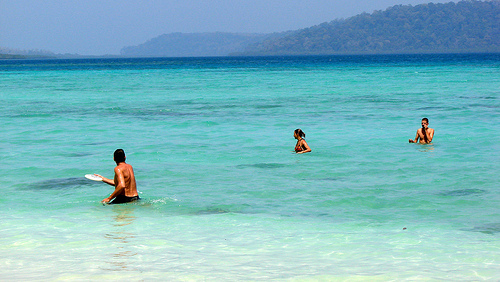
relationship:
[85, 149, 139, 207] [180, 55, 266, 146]
man in ocean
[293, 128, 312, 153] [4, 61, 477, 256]
person playing in water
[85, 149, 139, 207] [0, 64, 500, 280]
man playing in ocean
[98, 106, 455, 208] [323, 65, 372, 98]
people playing in water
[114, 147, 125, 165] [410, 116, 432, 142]
head of a man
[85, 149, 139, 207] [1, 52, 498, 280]
man in ocean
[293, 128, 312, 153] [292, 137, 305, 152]
person wearing a bathing suit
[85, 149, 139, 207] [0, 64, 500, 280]
man in ocean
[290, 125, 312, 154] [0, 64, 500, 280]
person in ocean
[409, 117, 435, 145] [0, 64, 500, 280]
man in ocean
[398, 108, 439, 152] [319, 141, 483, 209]
man yelling in water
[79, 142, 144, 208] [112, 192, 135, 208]
man wearing trunks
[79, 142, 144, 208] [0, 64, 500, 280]
man in ocean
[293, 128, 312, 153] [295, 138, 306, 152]
person wearing bathing suit